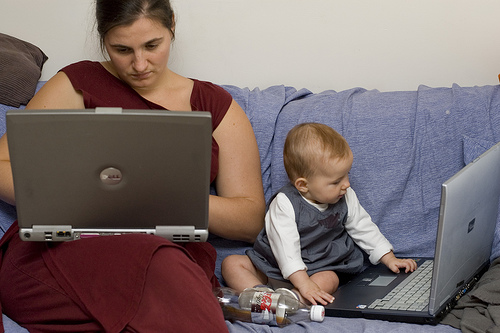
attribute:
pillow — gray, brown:
[0, 30, 49, 113]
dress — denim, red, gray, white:
[246, 194, 365, 279]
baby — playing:
[223, 119, 411, 313]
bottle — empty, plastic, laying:
[212, 287, 326, 330]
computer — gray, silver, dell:
[5, 106, 219, 242]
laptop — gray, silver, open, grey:
[323, 144, 497, 316]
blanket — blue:
[228, 85, 499, 259]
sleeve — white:
[268, 200, 307, 279]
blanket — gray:
[444, 251, 500, 332]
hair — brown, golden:
[280, 123, 350, 174]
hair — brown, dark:
[94, 2, 173, 32]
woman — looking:
[86, 2, 188, 95]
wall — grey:
[180, 9, 496, 78]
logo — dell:
[95, 163, 126, 191]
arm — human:
[202, 102, 271, 240]